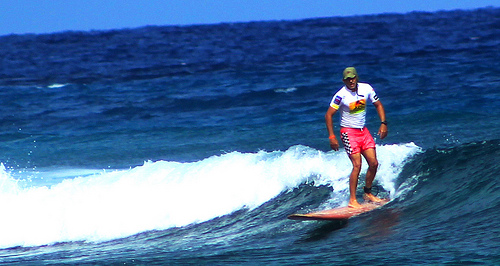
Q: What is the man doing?
A: Surfing.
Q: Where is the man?
A: In the ocean.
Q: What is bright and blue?
A: The ocean.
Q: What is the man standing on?
A: A board.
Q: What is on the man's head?
A: A hat.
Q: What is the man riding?
A: A wave.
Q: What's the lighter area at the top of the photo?
A: The sky.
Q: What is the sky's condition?
A: Clear.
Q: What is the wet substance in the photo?
A: Water.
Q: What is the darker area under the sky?
A: A body of water.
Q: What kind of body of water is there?
A: An ocean.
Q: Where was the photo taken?
A: On a beach.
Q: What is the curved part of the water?
A: A wave.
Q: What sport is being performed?
A: Surfing.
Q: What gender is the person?
A: Male.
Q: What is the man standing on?
A: A surfboard.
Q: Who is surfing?
A: A man.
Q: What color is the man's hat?
A: Green.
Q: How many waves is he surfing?
A: One.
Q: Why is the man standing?
A: To ride waves.